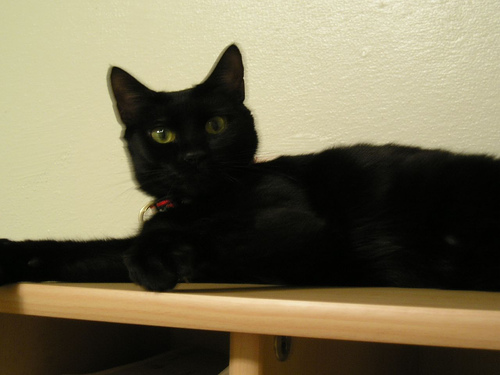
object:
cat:
[1, 44, 498, 295]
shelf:
[0, 277, 500, 372]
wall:
[1, 1, 498, 241]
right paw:
[0, 237, 28, 285]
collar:
[150, 197, 195, 209]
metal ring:
[138, 202, 157, 222]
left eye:
[204, 116, 227, 136]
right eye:
[149, 127, 176, 143]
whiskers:
[98, 171, 181, 198]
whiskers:
[207, 145, 286, 163]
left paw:
[122, 231, 176, 293]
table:
[1, 279, 500, 372]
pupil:
[160, 132, 169, 142]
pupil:
[212, 118, 219, 131]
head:
[105, 43, 258, 195]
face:
[141, 111, 254, 179]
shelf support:
[274, 335, 294, 363]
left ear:
[203, 43, 246, 104]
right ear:
[107, 65, 156, 128]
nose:
[183, 151, 205, 164]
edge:
[1, 281, 500, 350]